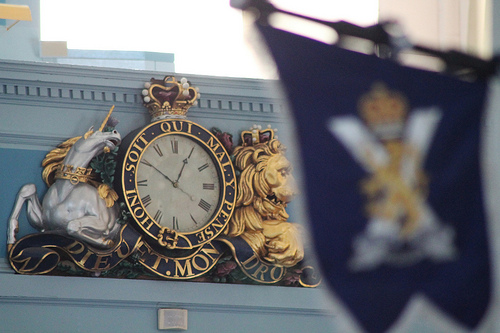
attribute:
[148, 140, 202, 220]
clock — black, roman, gold, atop, here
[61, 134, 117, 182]
unicorn — white, silver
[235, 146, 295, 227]
lion — gold, here, wearing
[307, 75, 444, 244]
flag — black, hanging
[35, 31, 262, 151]
buildings — grouped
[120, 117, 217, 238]
lettering — gold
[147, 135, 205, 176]
numeral — present, here, roman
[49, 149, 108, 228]
horse — silver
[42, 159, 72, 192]
hair — gold